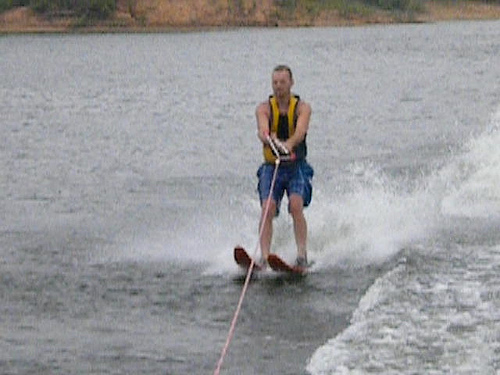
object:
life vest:
[262, 91, 307, 163]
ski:
[266, 253, 308, 272]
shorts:
[278, 161, 315, 207]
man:
[255, 64, 312, 269]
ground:
[324, 172, 375, 223]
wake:
[299, 104, 500, 375]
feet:
[259, 253, 308, 271]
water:
[36, 84, 171, 209]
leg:
[257, 163, 275, 259]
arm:
[287, 104, 312, 144]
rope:
[211, 157, 284, 375]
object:
[263, 134, 291, 161]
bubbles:
[303, 273, 500, 374]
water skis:
[234, 246, 306, 273]